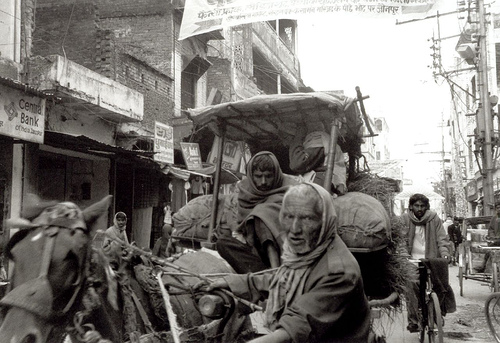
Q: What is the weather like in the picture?
A: It is clear.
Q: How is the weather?
A: It is clear.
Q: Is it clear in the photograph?
A: Yes, it is clear.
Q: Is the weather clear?
A: Yes, it is clear.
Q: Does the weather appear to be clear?
A: Yes, it is clear.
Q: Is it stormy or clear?
A: It is clear.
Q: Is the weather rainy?
A: No, it is clear.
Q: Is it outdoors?
A: Yes, it is outdoors.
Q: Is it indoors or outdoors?
A: It is outdoors.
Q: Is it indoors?
A: No, it is outdoors.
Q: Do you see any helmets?
A: No, there are no helmets.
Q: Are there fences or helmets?
A: No, there are no helmets or fences.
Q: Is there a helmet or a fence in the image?
A: No, there are no helmets or fences.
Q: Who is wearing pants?
A: The man is wearing pants.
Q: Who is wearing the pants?
A: The man is wearing pants.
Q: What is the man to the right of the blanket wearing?
A: The man is wearing pants.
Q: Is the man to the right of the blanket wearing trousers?
A: Yes, the man is wearing trousers.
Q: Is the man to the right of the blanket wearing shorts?
A: No, the man is wearing trousers.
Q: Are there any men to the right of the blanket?
A: Yes, there is a man to the right of the blanket.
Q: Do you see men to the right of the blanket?
A: Yes, there is a man to the right of the blanket.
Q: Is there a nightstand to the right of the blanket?
A: No, there is a man to the right of the blanket.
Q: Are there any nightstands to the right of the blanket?
A: No, there is a man to the right of the blanket.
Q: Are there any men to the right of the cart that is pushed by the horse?
A: Yes, there is a man to the right of the cart.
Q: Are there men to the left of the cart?
A: No, the man is to the right of the cart.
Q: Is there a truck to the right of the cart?
A: No, there is a man to the right of the cart.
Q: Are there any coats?
A: Yes, there is a coat.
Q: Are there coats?
A: Yes, there is a coat.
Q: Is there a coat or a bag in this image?
A: Yes, there is a coat.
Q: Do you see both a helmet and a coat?
A: No, there is a coat but no helmets.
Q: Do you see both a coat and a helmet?
A: No, there is a coat but no helmets.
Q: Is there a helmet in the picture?
A: No, there are no helmets.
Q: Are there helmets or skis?
A: No, there are no helmets or skis.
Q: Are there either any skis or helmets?
A: No, there are no helmets or skis.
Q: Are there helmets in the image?
A: No, there are no helmets.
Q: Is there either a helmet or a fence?
A: No, there are no helmets or fences.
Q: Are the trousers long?
A: Yes, the trousers are long.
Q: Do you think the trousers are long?
A: Yes, the trousers are long.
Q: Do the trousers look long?
A: Yes, the trousers are long.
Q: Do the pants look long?
A: Yes, the pants are long.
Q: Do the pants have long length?
A: Yes, the pants are long.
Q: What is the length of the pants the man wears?
A: The pants are long.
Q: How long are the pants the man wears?
A: The pants are long.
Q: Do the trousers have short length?
A: No, the trousers are long.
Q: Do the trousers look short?
A: No, the trousers are long.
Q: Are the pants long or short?
A: The pants are long.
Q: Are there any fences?
A: No, there are no fences.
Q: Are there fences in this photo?
A: No, there are no fences.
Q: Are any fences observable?
A: No, there are no fences.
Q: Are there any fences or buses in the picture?
A: No, there are no fences or buses.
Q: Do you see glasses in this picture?
A: No, there are no glasses.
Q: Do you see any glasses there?
A: No, there are no glasses.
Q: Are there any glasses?
A: No, there are no glasses.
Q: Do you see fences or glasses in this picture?
A: No, there are no glasses or fences.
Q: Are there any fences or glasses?
A: No, there are no glasses or fences.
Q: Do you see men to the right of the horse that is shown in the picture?
A: Yes, there is a man to the right of the horse.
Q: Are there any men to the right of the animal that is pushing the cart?
A: Yes, there is a man to the right of the horse.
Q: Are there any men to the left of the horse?
A: No, the man is to the right of the horse.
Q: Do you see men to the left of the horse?
A: No, the man is to the right of the horse.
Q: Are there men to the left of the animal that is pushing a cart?
A: No, the man is to the right of the horse.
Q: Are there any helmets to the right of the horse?
A: No, there is a man to the right of the horse.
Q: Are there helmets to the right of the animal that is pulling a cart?
A: No, there is a man to the right of the horse.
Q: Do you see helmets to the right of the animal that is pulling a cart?
A: No, there is a man to the right of the horse.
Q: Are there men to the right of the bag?
A: Yes, there is a man to the right of the bag.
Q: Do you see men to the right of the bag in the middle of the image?
A: Yes, there is a man to the right of the bag.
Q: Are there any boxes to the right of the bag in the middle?
A: No, there is a man to the right of the bag.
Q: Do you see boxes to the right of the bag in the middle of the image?
A: No, there is a man to the right of the bag.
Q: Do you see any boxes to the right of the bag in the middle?
A: No, there is a man to the right of the bag.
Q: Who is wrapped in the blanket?
A: The man is wrapped in the blanket.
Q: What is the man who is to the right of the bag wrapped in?
A: The man is wrapped in a blanket.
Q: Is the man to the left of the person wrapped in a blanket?
A: Yes, the man is wrapped in a blanket.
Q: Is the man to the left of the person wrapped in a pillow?
A: No, the man is wrapped in a blanket.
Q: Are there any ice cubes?
A: No, there are no ice cubes.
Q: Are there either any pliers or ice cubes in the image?
A: No, there are no ice cubes or pliers.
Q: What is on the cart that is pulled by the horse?
A: The straw is on the cart.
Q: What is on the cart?
A: The straw is on the cart.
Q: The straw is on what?
A: The straw is on the cart.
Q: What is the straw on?
A: The straw is on the cart.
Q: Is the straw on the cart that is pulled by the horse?
A: Yes, the straw is on the cart.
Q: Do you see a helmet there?
A: No, there are no helmets.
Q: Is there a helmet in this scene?
A: No, there are no helmets.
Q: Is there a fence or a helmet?
A: No, there are no helmets or fences.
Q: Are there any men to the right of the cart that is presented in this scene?
A: Yes, there is a man to the right of the cart.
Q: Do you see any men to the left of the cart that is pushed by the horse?
A: No, the man is to the right of the cart.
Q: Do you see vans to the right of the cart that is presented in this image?
A: No, there is a man to the right of the cart.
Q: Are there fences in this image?
A: No, there are no fences.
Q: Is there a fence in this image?
A: No, there are no fences.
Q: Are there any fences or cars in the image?
A: No, there are no fences or cars.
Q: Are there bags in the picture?
A: Yes, there is a bag.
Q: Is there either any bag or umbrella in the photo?
A: Yes, there is a bag.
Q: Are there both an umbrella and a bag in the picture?
A: No, there is a bag but no umbrellas.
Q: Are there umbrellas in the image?
A: No, there are no umbrellas.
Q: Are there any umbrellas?
A: No, there are no umbrellas.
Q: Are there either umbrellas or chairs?
A: No, there are no umbrellas or chairs.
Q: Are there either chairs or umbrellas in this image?
A: No, there are no umbrellas or chairs.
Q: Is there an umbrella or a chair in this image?
A: No, there are no umbrellas or chairs.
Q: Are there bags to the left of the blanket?
A: Yes, there is a bag to the left of the blanket.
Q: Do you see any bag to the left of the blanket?
A: Yes, there is a bag to the left of the blanket.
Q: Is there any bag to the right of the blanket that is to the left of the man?
A: No, the bag is to the left of the blanket.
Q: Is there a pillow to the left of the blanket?
A: No, there is a bag to the left of the blanket.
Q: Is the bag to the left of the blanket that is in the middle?
A: Yes, the bag is to the left of the blanket.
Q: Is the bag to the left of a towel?
A: No, the bag is to the left of the blanket.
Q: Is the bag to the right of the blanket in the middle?
A: No, the bag is to the left of the blanket.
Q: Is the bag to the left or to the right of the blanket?
A: The bag is to the left of the blanket.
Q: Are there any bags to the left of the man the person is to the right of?
A: Yes, there is a bag to the left of the man.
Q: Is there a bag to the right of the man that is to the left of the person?
A: No, the bag is to the left of the man.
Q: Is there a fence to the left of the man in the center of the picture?
A: No, there is a bag to the left of the man.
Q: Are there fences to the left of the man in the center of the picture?
A: No, there is a bag to the left of the man.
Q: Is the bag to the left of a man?
A: Yes, the bag is to the left of a man.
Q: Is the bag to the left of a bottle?
A: No, the bag is to the left of a man.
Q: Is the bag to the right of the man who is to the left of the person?
A: No, the bag is to the left of the man.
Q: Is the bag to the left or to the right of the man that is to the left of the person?
A: The bag is to the left of the man.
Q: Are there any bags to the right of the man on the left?
A: Yes, there is a bag to the right of the man.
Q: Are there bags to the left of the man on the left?
A: No, the bag is to the right of the man.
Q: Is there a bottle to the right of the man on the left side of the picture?
A: No, there is a bag to the right of the man.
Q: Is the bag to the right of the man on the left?
A: Yes, the bag is to the right of the man.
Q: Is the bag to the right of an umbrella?
A: No, the bag is to the right of the man.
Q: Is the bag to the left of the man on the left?
A: No, the bag is to the right of the man.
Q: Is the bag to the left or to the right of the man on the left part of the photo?
A: The bag is to the right of the man.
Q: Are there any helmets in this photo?
A: No, there are no helmets.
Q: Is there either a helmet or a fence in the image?
A: No, there are no helmets or fences.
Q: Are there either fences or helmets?
A: No, there are no helmets or fences.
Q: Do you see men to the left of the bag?
A: Yes, there is a man to the left of the bag.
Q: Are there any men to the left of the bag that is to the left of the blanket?
A: Yes, there is a man to the left of the bag.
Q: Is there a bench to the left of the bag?
A: No, there is a man to the left of the bag.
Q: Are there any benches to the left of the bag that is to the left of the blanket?
A: No, there is a man to the left of the bag.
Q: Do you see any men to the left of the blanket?
A: Yes, there is a man to the left of the blanket.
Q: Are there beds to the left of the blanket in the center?
A: No, there is a man to the left of the blanket.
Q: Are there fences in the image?
A: No, there are no fences.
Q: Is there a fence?
A: No, there are no fences.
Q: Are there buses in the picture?
A: No, there are no buses.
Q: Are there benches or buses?
A: No, there are no buses or benches.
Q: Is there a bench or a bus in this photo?
A: No, there are no buses or benches.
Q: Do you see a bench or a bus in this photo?
A: No, there are no buses or benches.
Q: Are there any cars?
A: No, there are no cars.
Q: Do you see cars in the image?
A: No, there are no cars.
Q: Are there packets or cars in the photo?
A: No, there are no cars or packets.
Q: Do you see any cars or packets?
A: No, there are no cars or packets.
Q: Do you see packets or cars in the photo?
A: No, there are no cars or packets.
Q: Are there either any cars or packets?
A: No, there are no cars or packets.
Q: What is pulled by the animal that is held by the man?
A: The cart is pulled by the horse.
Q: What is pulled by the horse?
A: The cart is pulled by the horse.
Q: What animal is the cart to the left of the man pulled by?
A: The cart is pulled by the horse.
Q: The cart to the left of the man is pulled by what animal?
A: The cart is pulled by the horse.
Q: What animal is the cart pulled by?
A: The cart is pulled by the horse.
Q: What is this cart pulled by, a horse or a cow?
A: The cart is pulled by a horse.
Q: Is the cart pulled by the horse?
A: Yes, the cart is pulled by the horse.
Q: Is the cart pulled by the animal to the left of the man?
A: Yes, the cart is pulled by the horse.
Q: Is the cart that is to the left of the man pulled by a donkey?
A: No, the cart is pulled by the horse.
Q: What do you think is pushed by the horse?
A: The cart is pushed by the horse.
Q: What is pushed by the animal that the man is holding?
A: The cart is pushed by the horse.